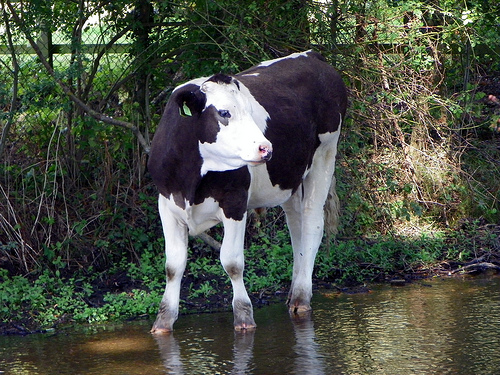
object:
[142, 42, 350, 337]
cow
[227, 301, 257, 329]
hoof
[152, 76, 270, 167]
head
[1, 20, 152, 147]
fence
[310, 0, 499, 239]
sun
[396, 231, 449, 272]
grass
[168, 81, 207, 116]
ear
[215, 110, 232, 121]
eye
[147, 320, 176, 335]
hooves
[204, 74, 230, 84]
spot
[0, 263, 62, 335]
plants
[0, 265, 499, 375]
water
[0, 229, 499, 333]
weeds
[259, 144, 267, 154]
nostril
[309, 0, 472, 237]
light